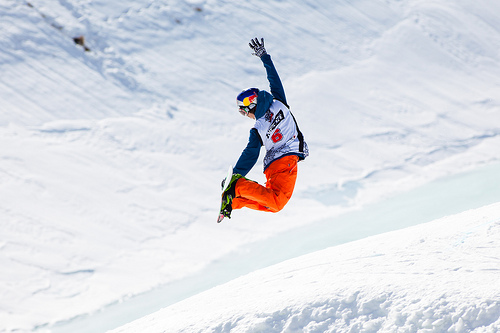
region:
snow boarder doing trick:
[197, 21, 314, 229]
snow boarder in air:
[192, 33, 306, 228]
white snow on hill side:
[22, 135, 132, 199]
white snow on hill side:
[61, 219, 138, 259]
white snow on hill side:
[147, 243, 241, 305]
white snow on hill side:
[244, 266, 355, 323]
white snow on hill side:
[25, 79, 109, 137]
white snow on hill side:
[158, 31, 196, 78]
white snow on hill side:
[330, 28, 387, 93]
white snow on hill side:
[385, 85, 462, 145]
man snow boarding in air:
[149, 20, 363, 243]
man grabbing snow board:
[161, 20, 325, 222]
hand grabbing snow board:
[195, 145, 272, 222]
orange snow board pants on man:
[211, 146, 312, 241]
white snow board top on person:
[255, 103, 305, 157]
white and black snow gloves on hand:
[245, 34, 266, 57]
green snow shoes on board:
[225, 171, 240, 227]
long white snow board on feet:
[215, 158, 244, 234]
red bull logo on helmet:
[238, 83, 265, 115]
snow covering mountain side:
[0, 38, 195, 271]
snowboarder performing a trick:
[210, 23, 313, 228]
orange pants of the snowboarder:
[232, 166, 299, 216]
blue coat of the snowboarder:
[220, 63, 303, 160]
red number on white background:
[269, 127, 284, 141]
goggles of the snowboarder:
[237, 103, 251, 114]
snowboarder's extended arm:
[245, 35, 294, 95]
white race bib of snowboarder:
[254, 107, 300, 150]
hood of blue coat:
[252, 94, 271, 114]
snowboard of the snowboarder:
[212, 162, 237, 230]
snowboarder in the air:
[167, 22, 318, 231]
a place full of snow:
[285, 257, 455, 314]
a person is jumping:
[191, 29, 319, 234]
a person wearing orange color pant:
[229, 150, 301, 215]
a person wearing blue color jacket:
[233, 87, 305, 154]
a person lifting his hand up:
[251, 35, 294, 94]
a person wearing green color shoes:
[217, 170, 238, 222]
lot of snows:
[304, 273, 458, 319]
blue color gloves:
[244, 34, 274, 63]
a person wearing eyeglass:
[235, 107, 251, 112]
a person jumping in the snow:
[65, 24, 417, 284]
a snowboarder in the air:
[173, 29, 338, 230]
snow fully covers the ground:
[12, 0, 499, 325]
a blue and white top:
[171, 37, 326, 174]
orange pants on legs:
[208, 150, 312, 239]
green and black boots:
[224, 168, 244, 235]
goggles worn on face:
[238, 105, 261, 125]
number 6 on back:
[265, 129, 295, 151]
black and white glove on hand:
[246, 32, 275, 59]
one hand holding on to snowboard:
[211, 174, 236, 199]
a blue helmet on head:
[231, 75, 266, 111]